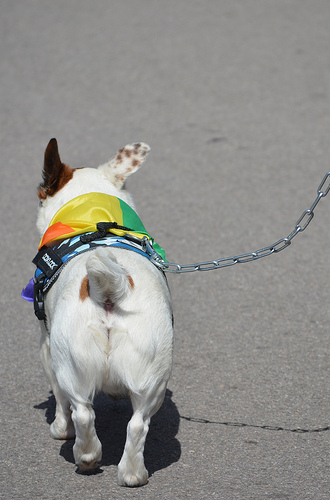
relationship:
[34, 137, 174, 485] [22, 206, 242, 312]
dog walking on leash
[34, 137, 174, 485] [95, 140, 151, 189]
dog has ear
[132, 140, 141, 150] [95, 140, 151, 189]
spot on ear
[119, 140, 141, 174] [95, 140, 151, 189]
spot on ear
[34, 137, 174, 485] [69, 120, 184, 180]
dog has ear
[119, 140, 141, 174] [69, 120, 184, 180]
spot on ear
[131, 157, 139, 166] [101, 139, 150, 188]
spots on dog's ear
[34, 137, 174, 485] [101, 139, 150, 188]
dog has dog's ear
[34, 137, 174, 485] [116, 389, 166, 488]
dog has leg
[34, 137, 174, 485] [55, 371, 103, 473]
dog has leg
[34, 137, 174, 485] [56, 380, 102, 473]
dog has leg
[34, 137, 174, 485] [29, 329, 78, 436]
dog has front leg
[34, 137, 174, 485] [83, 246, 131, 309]
dog has tail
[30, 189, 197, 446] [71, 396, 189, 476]
dog casting shadow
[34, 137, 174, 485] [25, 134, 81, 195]
dog has ear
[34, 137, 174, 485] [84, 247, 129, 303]
dog has tail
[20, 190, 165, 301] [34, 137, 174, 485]
fabric on dog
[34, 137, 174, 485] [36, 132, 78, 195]
dog has ear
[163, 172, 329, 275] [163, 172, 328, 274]
chain on chain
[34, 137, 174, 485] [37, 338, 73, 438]
dog has leg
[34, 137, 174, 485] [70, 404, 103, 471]
dog has leg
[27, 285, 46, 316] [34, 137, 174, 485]
buckle on dog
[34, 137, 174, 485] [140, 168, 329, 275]
dog connected to chain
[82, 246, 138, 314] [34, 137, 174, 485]
tail of dog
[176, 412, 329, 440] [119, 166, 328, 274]
shadow of chain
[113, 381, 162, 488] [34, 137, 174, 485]
leg of dog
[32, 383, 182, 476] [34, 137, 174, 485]
shadow of dog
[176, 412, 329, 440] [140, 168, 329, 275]
shadow of chain